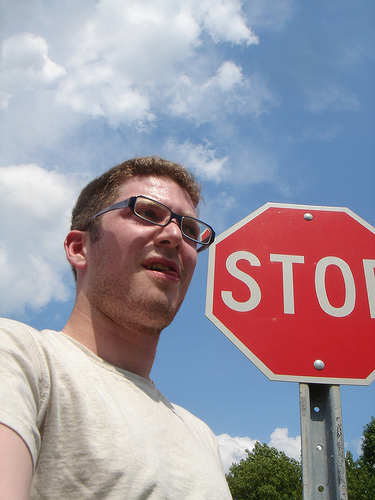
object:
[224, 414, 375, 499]
trees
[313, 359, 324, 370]
bolt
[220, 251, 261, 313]
letter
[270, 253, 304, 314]
letter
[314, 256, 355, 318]
letter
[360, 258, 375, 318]
letter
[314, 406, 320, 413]
hole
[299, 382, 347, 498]
metal pole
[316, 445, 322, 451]
hole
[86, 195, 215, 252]
eye glasses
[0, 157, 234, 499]
man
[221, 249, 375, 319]
stop sign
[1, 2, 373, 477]
sky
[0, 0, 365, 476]
cloud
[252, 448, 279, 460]
leaves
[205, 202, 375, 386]
sign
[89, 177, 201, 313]
face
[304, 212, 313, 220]
bolts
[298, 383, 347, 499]
pole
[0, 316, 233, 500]
shirt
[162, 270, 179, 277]
tongue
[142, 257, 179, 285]
mouth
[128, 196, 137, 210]
frame